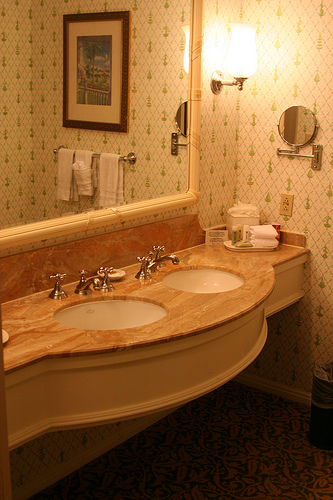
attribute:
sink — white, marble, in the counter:
[50, 293, 170, 331]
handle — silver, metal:
[48, 268, 71, 302]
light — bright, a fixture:
[208, 23, 259, 95]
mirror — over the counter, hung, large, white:
[0, 0, 205, 251]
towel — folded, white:
[96, 150, 125, 210]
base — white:
[4, 254, 310, 456]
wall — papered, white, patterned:
[201, 3, 332, 400]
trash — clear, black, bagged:
[308, 361, 332, 445]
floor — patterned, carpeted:
[28, 378, 331, 498]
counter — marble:
[3, 244, 313, 373]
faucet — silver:
[149, 246, 180, 276]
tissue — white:
[227, 199, 262, 238]